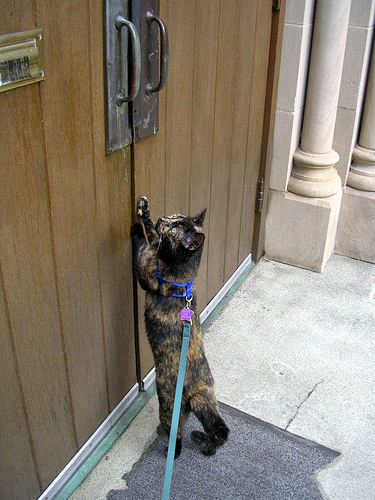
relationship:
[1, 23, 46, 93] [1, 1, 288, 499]
slot in door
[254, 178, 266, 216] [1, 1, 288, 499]
hinge of door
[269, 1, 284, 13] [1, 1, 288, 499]
hinge of door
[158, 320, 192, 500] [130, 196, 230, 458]
leash on cat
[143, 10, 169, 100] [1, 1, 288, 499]
handle of door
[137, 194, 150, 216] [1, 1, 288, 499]
paw on door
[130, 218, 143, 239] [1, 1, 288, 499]
paw on door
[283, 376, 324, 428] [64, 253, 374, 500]
crack in concrete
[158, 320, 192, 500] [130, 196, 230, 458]
leash of cat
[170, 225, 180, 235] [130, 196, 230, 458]
eye of cat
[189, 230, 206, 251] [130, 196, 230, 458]
ear of cat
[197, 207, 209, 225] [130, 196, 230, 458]
ear of cat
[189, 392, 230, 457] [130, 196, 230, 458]
tail of cat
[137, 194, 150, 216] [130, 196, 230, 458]
paw of cat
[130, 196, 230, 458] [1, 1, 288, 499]
cat pawing at door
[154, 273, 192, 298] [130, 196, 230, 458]
harness on cat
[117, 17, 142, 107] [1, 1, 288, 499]
handle of door